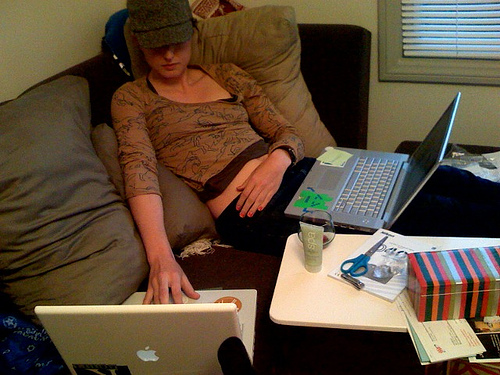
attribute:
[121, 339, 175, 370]
logo — silver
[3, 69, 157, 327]
pillow — fluffy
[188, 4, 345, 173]
pillow — fluffy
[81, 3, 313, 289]
girl — sitting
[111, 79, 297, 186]
shirt — brown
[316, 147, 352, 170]
stickie note — yellow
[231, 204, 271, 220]
nails — red 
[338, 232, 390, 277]
scissors — blue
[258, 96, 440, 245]
lap top — silver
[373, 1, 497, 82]
frame — wooden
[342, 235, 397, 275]
scissors — blue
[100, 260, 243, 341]
laptop — open, white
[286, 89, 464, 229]
laptop — open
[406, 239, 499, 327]
box — red, blue, orange, striped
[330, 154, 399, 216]
keyboard — silver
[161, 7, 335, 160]
pillow — large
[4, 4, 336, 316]
pillow — large, fluffy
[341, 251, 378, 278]
scissors — blue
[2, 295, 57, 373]
cloth — blue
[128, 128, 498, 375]
table — black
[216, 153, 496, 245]
pants — black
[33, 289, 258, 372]
laptop — tan